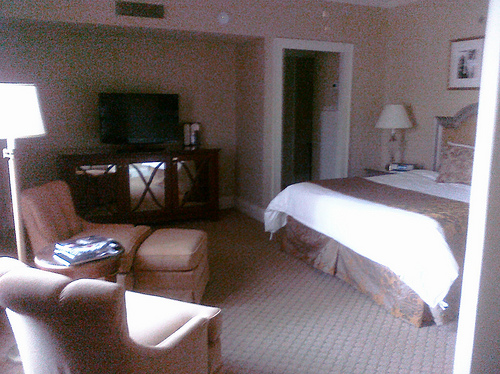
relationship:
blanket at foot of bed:
[264, 180, 459, 311] [263, 103, 478, 328]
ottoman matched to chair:
[132, 226, 212, 303] [18, 179, 151, 291]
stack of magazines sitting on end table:
[52, 234, 125, 265] [33, 243, 122, 285]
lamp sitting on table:
[373, 103, 414, 168] [365, 165, 422, 179]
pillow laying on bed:
[434, 140, 475, 186] [263, 103, 478, 328]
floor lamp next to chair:
[0, 82, 47, 264] [18, 179, 151, 291]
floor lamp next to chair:
[0, 82, 47, 264] [1, 255, 225, 374]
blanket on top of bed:
[279, 175, 469, 327] [263, 103, 478, 328]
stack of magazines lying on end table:
[52, 234, 125, 265] [33, 243, 122, 285]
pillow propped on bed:
[434, 140, 475, 186] [263, 103, 478, 328]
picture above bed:
[445, 36, 486, 92] [263, 103, 478, 328]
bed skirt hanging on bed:
[280, 215, 434, 328] [263, 103, 478, 328]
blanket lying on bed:
[264, 180, 459, 311] [263, 103, 478, 328]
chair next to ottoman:
[18, 179, 151, 291] [132, 226, 212, 303]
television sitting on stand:
[96, 91, 181, 153] [55, 147, 221, 224]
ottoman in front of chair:
[132, 226, 212, 303] [18, 179, 151, 291]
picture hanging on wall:
[445, 36, 486, 92] [376, 6, 488, 170]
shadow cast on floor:
[200, 253, 257, 306] [0, 206, 459, 374]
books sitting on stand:
[180, 121, 202, 147] [55, 147, 221, 224]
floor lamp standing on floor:
[0, 82, 47, 264] [0, 206, 459, 374]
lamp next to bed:
[373, 103, 414, 168] [263, 103, 478, 328]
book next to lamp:
[388, 161, 415, 172] [373, 103, 414, 168]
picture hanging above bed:
[445, 36, 486, 92] [263, 103, 478, 328]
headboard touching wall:
[432, 102, 479, 171] [376, 6, 488, 170]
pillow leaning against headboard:
[434, 140, 475, 186] [432, 102, 479, 171]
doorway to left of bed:
[267, 36, 355, 202] [263, 103, 478, 328]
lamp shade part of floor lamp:
[0, 82, 47, 140] [0, 82, 47, 264]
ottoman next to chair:
[132, 226, 212, 303] [18, 179, 151, 291]